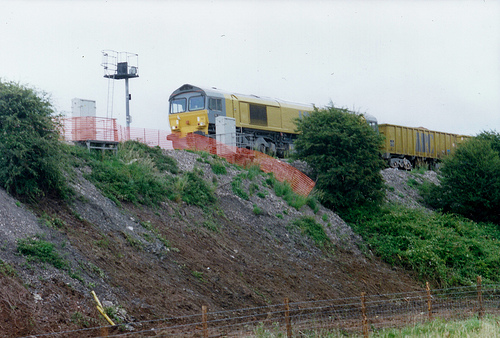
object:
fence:
[170, 134, 317, 194]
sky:
[0, 1, 500, 151]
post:
[357, 283, 370, 335]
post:
[420, 277, 435, 318]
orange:
[168, 121, 314, 198]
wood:
[283, 295, 293, 337]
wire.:
[207, 301, 285, 338]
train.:
[168, 82, 475, 174]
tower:
[99, 47, 140, 143]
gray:
[0, 1, 500, 150]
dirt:
[0, 150, 497, 337]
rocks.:
[0, 147, 496, 337]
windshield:
[170, 93, 207, 114]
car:
[376, 121, 479, 171]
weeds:
[339, 198, 500, 297]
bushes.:
[293, 102, 388, 220]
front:
[168, 82, 212, 153]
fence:
[26, 277, 500, 337]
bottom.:
[1, 275, 500, 335]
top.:
[101, 49, 140, 81]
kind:
[215, 115, 239, 165]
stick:
[91, 289, 117, 327]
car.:
[168, 83, 381, 167]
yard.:
[0, 80, 500, 336]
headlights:
[194, 116, 208, 131]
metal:
[215, 116, 240, 136]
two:
[281, 292, 372, 336]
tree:
[295, 98, 384, 219]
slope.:
[1, 143, 499, 337]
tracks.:
[271, 157, 455, 171]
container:
[213, 116, 238, 159]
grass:
[0, 135, 342, 283]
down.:
[0, 115, 446, 329]